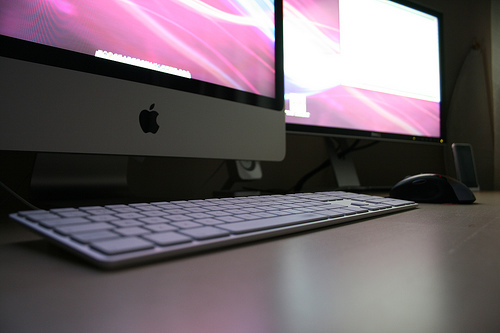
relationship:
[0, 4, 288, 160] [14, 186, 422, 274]
computer has keyboard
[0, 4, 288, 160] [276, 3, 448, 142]
computer has screen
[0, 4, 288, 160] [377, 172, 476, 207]
computer has mouse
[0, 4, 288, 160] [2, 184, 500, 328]
computer on desk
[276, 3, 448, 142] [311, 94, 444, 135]
screen reflects purple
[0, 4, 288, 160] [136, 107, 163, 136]
computer has apple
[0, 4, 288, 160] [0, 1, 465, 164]
computer has screens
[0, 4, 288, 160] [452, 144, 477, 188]
computer has speakers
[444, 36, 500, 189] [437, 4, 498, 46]
ironing board in background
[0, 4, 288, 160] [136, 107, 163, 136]
screen has apple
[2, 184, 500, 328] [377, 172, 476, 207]
desk has mouse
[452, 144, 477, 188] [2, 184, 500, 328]
speakers on desk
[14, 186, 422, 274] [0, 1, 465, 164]
keyboard near screens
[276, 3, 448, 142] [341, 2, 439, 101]
screen has words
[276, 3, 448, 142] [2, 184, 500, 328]
screen on desk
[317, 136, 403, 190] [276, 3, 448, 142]
stands below screen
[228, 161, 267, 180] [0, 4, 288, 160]
speaker on screen